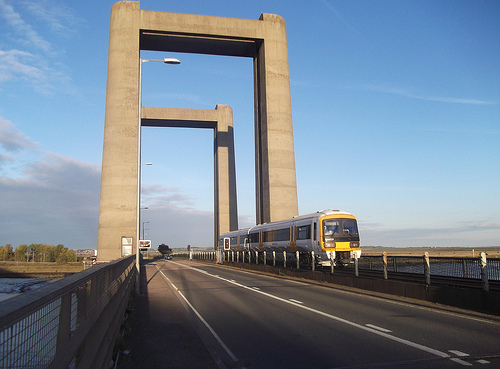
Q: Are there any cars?
A: No, there are no cars.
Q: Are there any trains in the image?
A: Yes, there is a train.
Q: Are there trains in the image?
A: Yes, there is a train.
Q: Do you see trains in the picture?
A: Yes, there is a train.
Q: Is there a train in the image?
A: Yes, there is a train.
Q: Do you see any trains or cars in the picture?
A: Yes, there is a train.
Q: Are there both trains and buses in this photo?
A: No, there is a train but no buses.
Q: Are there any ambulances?
A: No, there are no ambulances.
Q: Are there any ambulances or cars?
A: No, there are no ambulances or cars.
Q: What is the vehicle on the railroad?
A: The vehicle is a train.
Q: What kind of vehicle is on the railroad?
A: The vehicle is a train.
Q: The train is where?
A: The train is on the railroad.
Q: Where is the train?
A: The train is on the railroad.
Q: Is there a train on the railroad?
A: Yes, there is a train on the railroad.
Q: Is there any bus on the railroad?
A: No, there is a train on the railroad.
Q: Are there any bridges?
A: Yes, there is a bridge.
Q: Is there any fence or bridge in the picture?
A: Yes, there is a bridge.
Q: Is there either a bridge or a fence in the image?
A: Yes, there is a bridge.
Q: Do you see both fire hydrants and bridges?
A: No, there is a bridge but no fire hydrants.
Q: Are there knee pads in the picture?
A: No, there are no knee pads.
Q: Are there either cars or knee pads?
A: No, there are no knee pads or cars.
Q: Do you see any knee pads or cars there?
A: No, there are no knee pads or cars.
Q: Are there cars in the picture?
A: No, there are no cars.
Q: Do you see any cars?
A: No, there are no cars.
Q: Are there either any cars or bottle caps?
A: No, there are no cars or bottle caps.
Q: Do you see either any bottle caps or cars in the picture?
A: No, there are no cars or bottle caps.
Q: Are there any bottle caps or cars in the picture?
A: No, there are no cars or bottle caps.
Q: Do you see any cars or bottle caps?
A: No, there are no cars or bottle caps.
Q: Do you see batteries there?
A: No, there are no batteries.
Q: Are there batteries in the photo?
A: No, there are no batteries.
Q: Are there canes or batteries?
A: No, there are no batteries or canes.